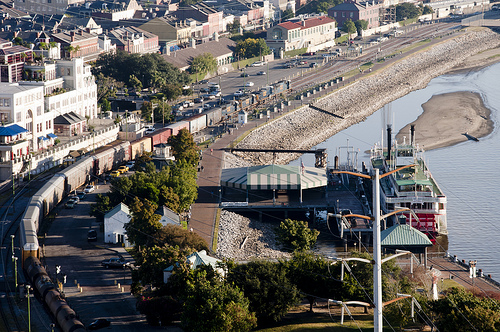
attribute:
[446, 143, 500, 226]
water — calm, clean, large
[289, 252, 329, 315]
tree — lush, green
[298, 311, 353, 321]
shadow — dark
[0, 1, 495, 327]
photo — downward, outdoor, daytime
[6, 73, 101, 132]
building — white, big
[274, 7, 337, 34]
roof — red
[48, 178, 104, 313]
road — curved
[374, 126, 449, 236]
ferry — red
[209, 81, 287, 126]
train — moving, long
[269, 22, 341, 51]
house — red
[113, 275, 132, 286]
parking lot — emtpy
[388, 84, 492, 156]
island — tan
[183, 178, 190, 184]
leaf — green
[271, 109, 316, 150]
gravel — tan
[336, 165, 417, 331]
pole — orange, tall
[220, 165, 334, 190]
roof — green, white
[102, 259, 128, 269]
car — parked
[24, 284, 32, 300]
tower — black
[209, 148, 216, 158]
person — walking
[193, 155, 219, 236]
walkway — green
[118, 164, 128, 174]
taxi — parked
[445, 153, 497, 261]
lake — calm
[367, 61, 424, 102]
stone — grey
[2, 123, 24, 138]
awning — blue